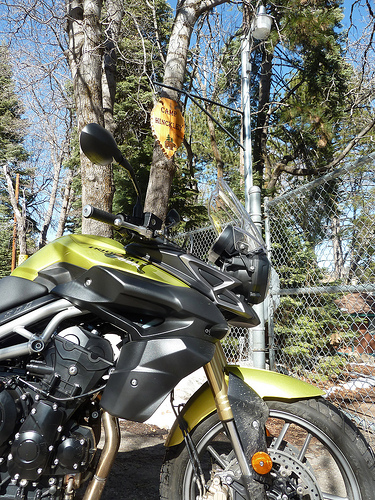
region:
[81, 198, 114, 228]
it is the handle bar on the bike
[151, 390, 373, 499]
the front tire of the motorcycle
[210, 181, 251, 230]
the windshield of the motorcycle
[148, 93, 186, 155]
a yellow sign is hanging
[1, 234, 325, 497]
a black and green motorcycle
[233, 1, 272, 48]
a lamp post in the background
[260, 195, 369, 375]
it is a fence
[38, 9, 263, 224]
a group of trees in the background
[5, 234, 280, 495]
black and light green motorcycle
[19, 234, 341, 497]
a bike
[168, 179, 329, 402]
a gray wired fence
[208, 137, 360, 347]
a gray wired fence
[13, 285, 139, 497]
bike's engine is black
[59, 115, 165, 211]
side mirror is black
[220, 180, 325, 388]
fence made of metal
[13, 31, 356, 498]
A motorcycle parked by a fence.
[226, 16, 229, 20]
this is the sky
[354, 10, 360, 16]
the sky is blue in color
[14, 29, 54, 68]
the sky has clouds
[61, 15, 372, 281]
these are some trees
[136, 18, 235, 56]
the trees are tall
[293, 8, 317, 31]
the leaves are green in color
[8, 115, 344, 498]
this is a motorcycle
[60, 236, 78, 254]
the motorcycle is yellow in color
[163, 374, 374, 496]
this is a wheel